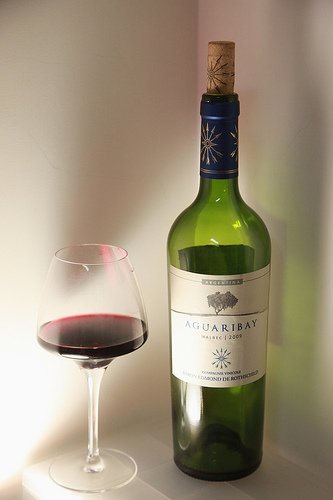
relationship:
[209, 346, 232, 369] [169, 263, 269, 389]
gold star in label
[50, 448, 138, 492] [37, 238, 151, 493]
base of glass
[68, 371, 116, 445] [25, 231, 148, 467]
stem of glass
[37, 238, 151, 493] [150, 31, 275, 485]
glass of wine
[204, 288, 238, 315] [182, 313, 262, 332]
logo on manufacturer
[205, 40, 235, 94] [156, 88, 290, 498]
cork on bottle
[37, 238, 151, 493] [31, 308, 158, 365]
glass of wine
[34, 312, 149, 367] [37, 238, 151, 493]
wine in glass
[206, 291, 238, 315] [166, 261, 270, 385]
logo on lable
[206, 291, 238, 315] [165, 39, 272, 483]
logo on bottle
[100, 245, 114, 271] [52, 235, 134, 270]
lipstick on glass rim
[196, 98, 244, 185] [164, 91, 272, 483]
label on bottle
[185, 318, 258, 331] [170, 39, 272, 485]
manufacturer on wine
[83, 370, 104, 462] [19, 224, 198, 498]
stem on glass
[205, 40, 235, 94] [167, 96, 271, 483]
cork in bottle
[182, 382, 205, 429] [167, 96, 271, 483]
reflection on bottle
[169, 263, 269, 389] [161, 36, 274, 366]
label on bottle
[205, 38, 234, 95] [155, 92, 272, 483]
cork in bottle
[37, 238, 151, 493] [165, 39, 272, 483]
glass beside bottle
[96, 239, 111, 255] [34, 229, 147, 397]
lipstick on glass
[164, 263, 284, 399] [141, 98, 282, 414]
label on bottle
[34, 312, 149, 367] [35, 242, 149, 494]
wine in empty glass